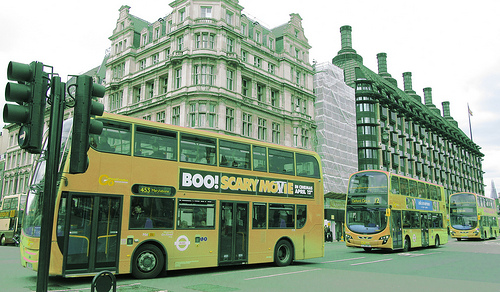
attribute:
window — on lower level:
[253, 201, 269, 229]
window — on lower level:
[266, 200, 296, 229]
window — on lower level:
[296, 202, 311, 229]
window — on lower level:
[174, 200, 214, 229]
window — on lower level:
[131, 195, 178, 226]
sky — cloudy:
[0, 1, 499, 200]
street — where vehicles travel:
[326, 224, 498, 288]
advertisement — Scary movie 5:
[159, 143, 266, 247]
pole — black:
[28, 157, 88, 277]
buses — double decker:
[109, 118, 384, 235]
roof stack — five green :
[328, 20, 362, 65]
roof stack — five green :
[372, 44, 393, 89]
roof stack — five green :
[397, 66, 421, 101]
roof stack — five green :
[420, 82, 438, 120]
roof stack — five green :
[438, 99, 456, 127]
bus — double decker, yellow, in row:
[21, 112, 326, 278]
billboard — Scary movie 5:
[176, 164, 320, 199]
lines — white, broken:
[224, 252, 454, 282]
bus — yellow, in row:
[451, 194, 497, 239]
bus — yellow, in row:
[345, 170, 449, 248]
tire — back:
[271, 235, 296, 265]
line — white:
[355, 255, 395, 264]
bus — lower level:
[14, 107, 332, 285]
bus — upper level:
[344, 152, 498, 258]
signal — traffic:
[9, 55, 34, 131]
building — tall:
[54, 10, 314, 257]